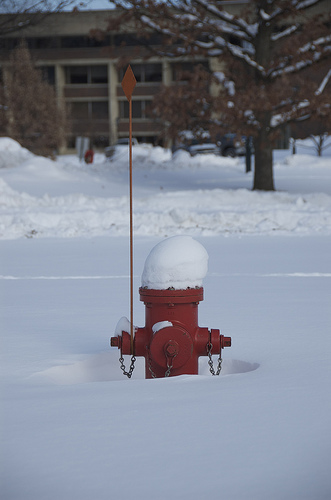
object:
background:
[5, 19, 322, 133]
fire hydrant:
[111, 236, 233, 379]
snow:
[139, 234, 211, 288]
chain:
[119, 354, 135, 379]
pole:
[129, 101, 133, 351]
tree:
[112, 0, 330, 199]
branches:
[266, 45, 330, 80]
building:
[3, 7, 291, 150]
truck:
[180, 129, 218, 156]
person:
[84, 144, 94, 165]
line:
[13, 266, 327, 280]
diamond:
[122, 64, 137, 97]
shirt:
[85, 150, 94, 164]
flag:
[122, 65, 138, 341]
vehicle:
[117, 138, 139, 146]